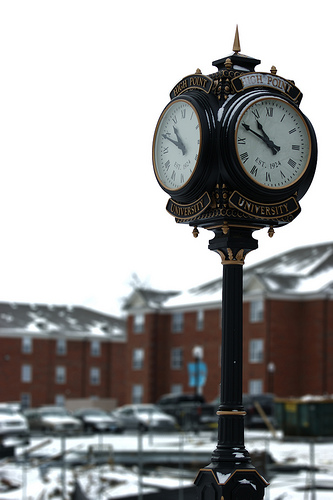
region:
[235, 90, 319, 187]
Roman numerals on clock.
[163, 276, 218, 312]
Snow on the roof.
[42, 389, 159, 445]
Cars in parking lot.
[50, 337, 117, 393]
Brick building in background.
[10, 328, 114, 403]
Multiple windows on building.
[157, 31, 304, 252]
Black metal trimmed in gold.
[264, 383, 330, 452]
Garbage dumpster in parking lot.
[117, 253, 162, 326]
Tree top behind building.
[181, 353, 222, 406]
Blue flag poster on pole.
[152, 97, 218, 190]
Background in clock is white.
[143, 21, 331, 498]
clocks on a pole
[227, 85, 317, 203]
clock is white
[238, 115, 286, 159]
hands of clock are black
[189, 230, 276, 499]
pole supporting clocks is fancy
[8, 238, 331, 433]
red buildings across the clocks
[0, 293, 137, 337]
building has black roof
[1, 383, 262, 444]
car parking on parking lot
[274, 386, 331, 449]
a dumpster on side of building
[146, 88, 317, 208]
two clocks giving the same hour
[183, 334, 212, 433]
a street light in front of building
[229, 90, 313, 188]
The face of the clock is white.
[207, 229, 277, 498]
The pole is black.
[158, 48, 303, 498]
The clock has gold accents.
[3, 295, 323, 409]
The building is brick.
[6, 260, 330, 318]
The roof is brown.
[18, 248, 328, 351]
The roof is snow covered.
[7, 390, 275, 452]
The cars are parked.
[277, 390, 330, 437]
The dumpster is green.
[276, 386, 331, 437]
The lid is on the dumpster.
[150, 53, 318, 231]
The clock has two faces.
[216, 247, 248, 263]
Golden leaf decorations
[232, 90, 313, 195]
face of clock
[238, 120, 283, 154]
hands of clock pointing to numerals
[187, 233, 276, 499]
tall base of clock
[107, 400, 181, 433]
light colored car in distance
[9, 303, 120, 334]
snow on a roof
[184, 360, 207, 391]
light blue banner hanging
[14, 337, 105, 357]
windows of third floor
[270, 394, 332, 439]
green trash dumpster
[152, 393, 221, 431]
dark colored pickup truck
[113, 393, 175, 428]
a grey car is parked.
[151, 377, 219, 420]
a dark grey truck is parked next to vehicles.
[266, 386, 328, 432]
a big green garbage dump.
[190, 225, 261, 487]
a black and brown pole.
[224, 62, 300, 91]
a clock says high point.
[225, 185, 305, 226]
a clock has university on the bottom.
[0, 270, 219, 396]
a big brown building.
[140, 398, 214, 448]
a thin grey fence.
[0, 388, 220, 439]
a bunch of vehicles are parked in the lot.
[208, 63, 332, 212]
a clock says 10:50.